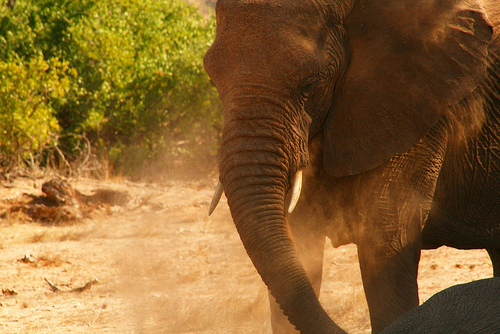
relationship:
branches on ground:
[8, 127, 117, 188] [9, 166, 490, 326]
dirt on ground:
[14, 170, 333, 333] [9, 166, 490, 326]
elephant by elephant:
[372, 275, 499, 332] [203, 1, 499, 331]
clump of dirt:
[22, 250, 92, 298] [14, 170, 333, 333]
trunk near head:
[219, 93, 339, 331] [201, 1, 361, 333]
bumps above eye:
[277, 35, 320, 78] [305, 83, 316, 91]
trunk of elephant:
[219, 93, 339, 331] [203, 1, 499, 331]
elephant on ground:
[203, 1, 499, 331] [9, 166, 490, 326]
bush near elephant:
[2, 2, 225, 182] [203, 1, 499, 331]